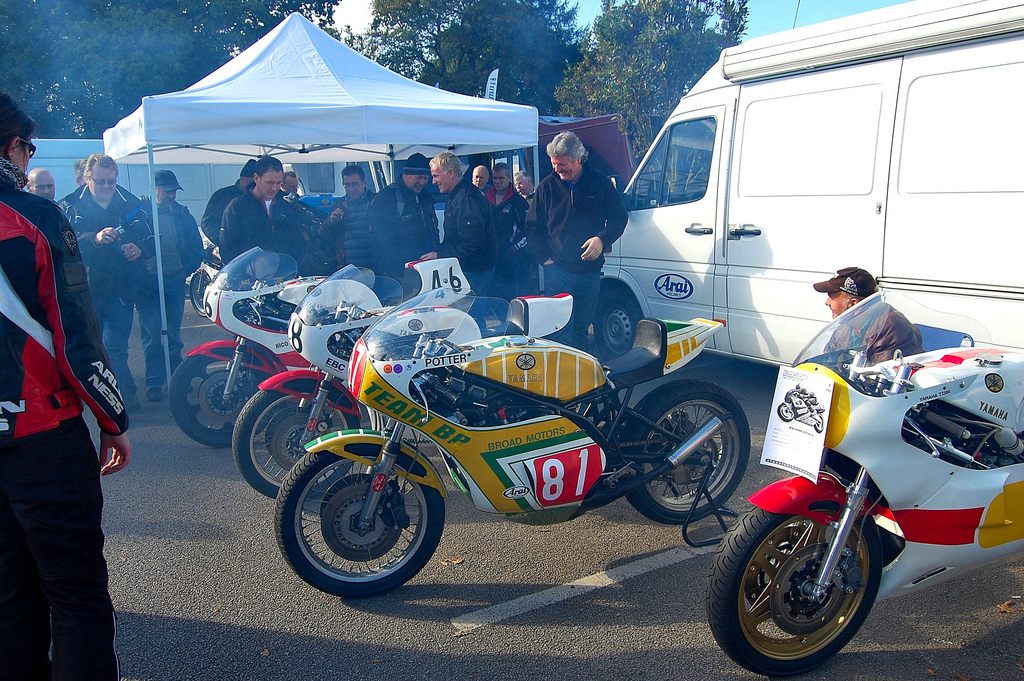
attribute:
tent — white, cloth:
[77, 1, 564, 475]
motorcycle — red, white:
[244, 287, 430, 499]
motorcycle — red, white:
[188, 265, 314, 473]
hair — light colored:
[545, 119, 597, 167]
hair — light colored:
[430, 157, 463, 186]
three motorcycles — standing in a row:
[166, 245, 752, 589]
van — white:
[587, 0, 1022, 385]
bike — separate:
[706, 337, 1022, 670]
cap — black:
[808, 255, 886, 299]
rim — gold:
[749, 532, 847, 653]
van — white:
[590, 80, 1020, 415]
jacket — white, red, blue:
[21, 80, 153, 677]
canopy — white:
[88, 41, 594, 214]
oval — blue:
[600, 260, 719, 341]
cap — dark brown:
[819, 238, 874, 303]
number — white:
[539, 456, 565, 502]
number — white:
[571, 441, 589, 498]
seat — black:
[597, 316, 667, 392]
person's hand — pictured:
[90, 411, 134, 479]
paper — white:
[757, 363, 846, 480]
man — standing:
[422, 137, 492, 289]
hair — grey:
[541, 126, 585, 159]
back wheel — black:
[619, 370, 758, 533]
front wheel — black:
[705, 489, 896, 673]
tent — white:
[98, 14, 539, 157]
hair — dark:
[239, 148, 292, 187]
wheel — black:
[714, 485, 890, 667]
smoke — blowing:
[18, 33, 325, 383]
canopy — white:
[102, 9, 537, 161]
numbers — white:
[528, 443, 591, 521]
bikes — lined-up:
[178, 236, 751, 619]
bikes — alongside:
[163, 251, 742, 606]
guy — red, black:
[1, 89, 136, 677]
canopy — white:
[129, 53, 499, 140]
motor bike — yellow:
[282, 307, 680, 550]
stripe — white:
[519, 603, 621, 638]